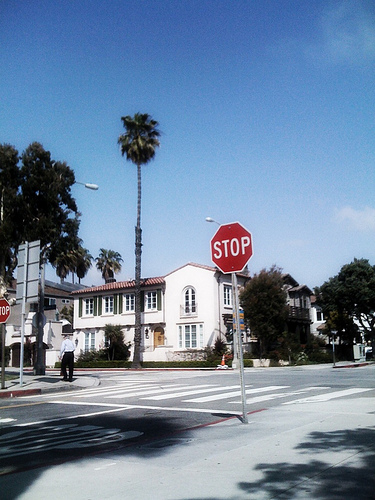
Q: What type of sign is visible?
A: Stop.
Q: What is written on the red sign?
A: Stop.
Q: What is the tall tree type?
A: Palm.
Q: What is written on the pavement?
A: Stop.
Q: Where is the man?
A: Sidewalk.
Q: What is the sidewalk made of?
A: Cement.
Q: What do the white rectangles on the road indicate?
A: Pedestrian crossing.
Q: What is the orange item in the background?
A: Safety cone.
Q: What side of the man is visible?
A: Back.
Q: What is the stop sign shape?
A: Octagon.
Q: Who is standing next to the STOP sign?
A: No one.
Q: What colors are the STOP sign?
A: Red, White.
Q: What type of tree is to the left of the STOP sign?
A: Palm tree.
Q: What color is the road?
A: Grey.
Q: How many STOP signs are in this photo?
A: Two.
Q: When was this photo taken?
A: Daytime.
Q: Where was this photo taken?
A: At an intersection.